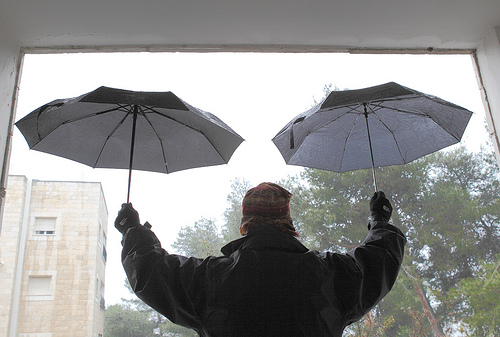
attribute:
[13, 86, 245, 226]
umbrella — black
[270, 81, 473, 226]
umbrella — black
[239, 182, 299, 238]
hat — red, patterned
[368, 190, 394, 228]
glove — black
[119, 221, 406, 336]
jacket — black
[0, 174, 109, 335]
building — large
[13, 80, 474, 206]
umbrellas — black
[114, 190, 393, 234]
gloves — black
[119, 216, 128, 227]
logo — white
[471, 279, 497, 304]
leaves — green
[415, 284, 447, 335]
trunk — brown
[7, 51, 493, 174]
sky — overcast, white